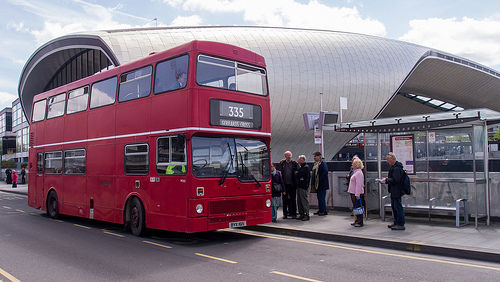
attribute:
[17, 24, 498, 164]
building — large, silver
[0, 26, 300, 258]
bus — red, double-decker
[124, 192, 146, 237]
wheel — black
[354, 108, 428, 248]
man — standing, reading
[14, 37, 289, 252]
bus — tall, red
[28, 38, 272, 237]
bus — double-decker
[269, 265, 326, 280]
painted lines — yellow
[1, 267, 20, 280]
line — yellow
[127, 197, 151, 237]
wheel — black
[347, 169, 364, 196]
shirt — pink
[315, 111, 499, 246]
stop — covered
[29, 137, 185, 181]
windows — bottom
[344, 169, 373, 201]
jacket — pink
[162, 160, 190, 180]
jacket — yellow-green